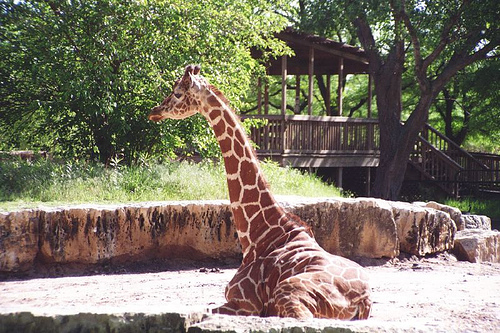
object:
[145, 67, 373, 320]
giraffe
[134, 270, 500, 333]
ground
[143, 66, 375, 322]
giraffe's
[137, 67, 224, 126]
head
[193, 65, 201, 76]
horns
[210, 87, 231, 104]
mane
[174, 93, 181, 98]
eye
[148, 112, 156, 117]
nose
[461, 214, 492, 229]
stone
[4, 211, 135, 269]
wall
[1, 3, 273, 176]
trees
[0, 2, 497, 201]
background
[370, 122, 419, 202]
trunk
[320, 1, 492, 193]
tree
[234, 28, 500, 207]
enclosure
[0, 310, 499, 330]
embankment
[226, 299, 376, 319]
down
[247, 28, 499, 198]
brown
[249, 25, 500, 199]
structure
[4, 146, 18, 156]
green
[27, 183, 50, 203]
grass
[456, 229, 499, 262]
blocks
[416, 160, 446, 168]
stair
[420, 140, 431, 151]
railings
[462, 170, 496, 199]
fencing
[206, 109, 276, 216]
neck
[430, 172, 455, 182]
stairs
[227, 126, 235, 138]
spots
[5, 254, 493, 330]
dirt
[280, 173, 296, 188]
bush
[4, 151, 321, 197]
hill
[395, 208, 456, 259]
rocks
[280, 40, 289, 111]
post